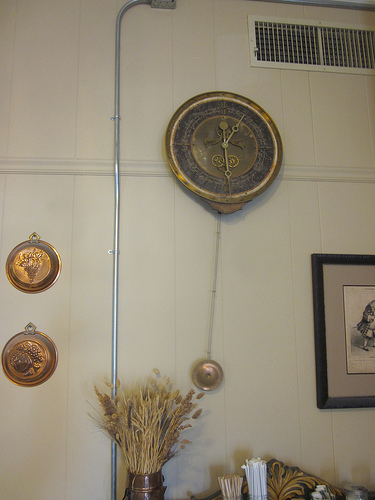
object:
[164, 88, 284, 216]
clock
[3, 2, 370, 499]
wall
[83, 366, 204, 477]
wheat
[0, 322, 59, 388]
bronze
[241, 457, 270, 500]
straws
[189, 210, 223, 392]
pendulum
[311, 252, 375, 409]
border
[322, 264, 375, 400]
picture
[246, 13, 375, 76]
vent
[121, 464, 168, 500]
vase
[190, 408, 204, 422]
plants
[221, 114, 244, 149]
arms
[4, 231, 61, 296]
pot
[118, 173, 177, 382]
paneling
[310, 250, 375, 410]
art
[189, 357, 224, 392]
bell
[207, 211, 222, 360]
stick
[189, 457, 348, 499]
sculpture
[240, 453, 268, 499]
wrappers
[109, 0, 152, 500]
pipe